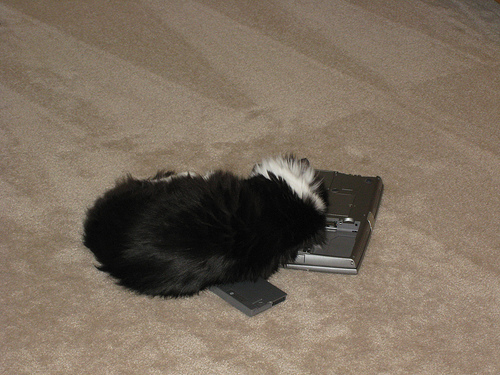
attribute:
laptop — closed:
[265, 131, 412, 324]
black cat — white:
[81, 151, 329, 296]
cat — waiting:
[114, 181, 327, 261]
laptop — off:
[290, 165, 395, 275]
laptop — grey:
[294, 161, 386, 275]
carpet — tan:
[86, 74, 119, 129]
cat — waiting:
[28, 136, 375, 313]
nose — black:
[296, 152, 311, 168]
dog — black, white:
[71, 142, 338, 304]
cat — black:
[38, 85, 315, 310]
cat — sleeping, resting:
[81, 151, 329, 303]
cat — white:
[79, 123, 391, 304]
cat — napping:
[79, 140, 341, 304]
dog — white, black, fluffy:
[78, 139, 333, 312]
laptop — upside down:
[267, 151, 372, 284]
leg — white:
[147, 152, 211, 200]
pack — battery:
[205, 276, 288, 316]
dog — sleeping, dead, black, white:
[86, 155, 329, 294]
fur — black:
[82, 152, 330, 305]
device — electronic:
[294, 169, 382, 271]